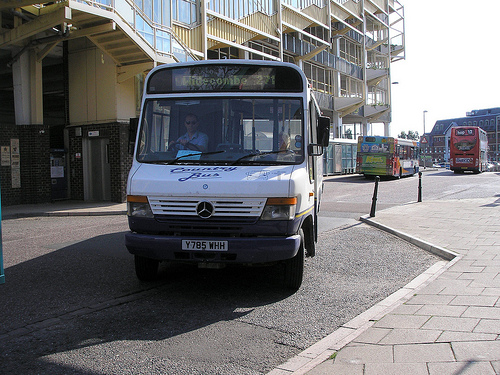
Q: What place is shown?
A: It is a street.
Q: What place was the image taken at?
A: It was taken at the street.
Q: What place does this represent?
A: It represents the street.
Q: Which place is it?
A: It is a street.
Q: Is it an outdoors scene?
A: Yes, it is outdoors.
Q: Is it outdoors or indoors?
A: It is outdoors.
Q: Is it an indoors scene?
A: No, it is outdoors.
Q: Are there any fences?
A: No, there are no fences.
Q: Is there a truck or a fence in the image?
A: No, there are no fences or trucks.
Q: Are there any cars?
A: No, there are no cars.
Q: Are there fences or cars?
A: No, there are no cars or fences.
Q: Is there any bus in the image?
A: Yes, there is a bus.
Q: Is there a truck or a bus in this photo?
A: Yes, there is a bus.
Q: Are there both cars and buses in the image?
A: No, there is a bus but no cars.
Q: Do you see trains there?
A: No, there are no trains.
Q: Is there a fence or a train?
A: No, there are no trains or fences.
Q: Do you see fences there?
A: No, there are no fences.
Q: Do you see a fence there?
A: No, there are no fences.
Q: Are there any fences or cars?
A: No, there are no fences or cars.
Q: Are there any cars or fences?
A: No, there are no fences or cars.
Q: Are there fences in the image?
A: No, there are no fences.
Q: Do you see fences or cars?
A: No, there are no fences or cars.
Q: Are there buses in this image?
A: Yes, there is a bus.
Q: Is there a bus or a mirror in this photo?
A: Yes, there is a bus.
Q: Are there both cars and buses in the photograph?
A: No, there is a bus but no cars.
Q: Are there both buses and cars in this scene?
A: No, there is a bus but no cars.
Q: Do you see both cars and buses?
A: No, there is a bus but no cars.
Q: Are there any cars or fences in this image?
A: No, there are no fences or cars.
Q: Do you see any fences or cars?
A: No, there are no fences or cars.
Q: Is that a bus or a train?
A: That is a bus.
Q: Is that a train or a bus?
A: That is a bus.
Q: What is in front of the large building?
A: The bus is in front of the building.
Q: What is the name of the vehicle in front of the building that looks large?
A: The vehicle is a bus.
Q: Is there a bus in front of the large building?
A: Yes, there is a bus in front of the building.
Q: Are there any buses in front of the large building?
A: Yes, there is a bus in front of the building.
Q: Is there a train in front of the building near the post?
A: No, there is a bus in front of the building.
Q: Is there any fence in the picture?
A: No, there are no fences.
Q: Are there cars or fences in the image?
A: No, there are no fences or cars.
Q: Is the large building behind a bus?
A: Yes, the building is behind a bus.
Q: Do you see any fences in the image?
A: No, there are no fences.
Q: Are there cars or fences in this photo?
A: No, there are no fences or cars.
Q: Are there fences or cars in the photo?
A: No, there are no fences or cars.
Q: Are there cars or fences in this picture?
A: No, there are no cars or fences.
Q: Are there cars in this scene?
A: No, there are no cars.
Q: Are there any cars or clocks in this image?
A: No, there are no cars or clocks.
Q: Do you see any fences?
A: No, there are no fences.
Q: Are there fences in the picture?
A: No, there are no fences.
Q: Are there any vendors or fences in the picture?
A: No, there are no fences or vendors.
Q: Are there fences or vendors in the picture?
A: No, there are no fences or vendors.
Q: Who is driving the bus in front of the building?
A: The driver is driving the bus.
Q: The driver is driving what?
A: The driver is driving the bus.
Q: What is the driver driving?
A: The driver is driving the bus.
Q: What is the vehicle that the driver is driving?
A: The vehicle is a bus.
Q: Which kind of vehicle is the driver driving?
A: The driver is driving the bus.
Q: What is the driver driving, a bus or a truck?
A: The driver is driving a bus.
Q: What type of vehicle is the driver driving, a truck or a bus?
A: The driver is driving a bus.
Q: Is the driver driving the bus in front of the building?
A: Yes, the driver is driving the bus.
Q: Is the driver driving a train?
A: No, the driver is driving the bus.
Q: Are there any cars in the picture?
A: No, there are no cars.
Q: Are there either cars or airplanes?
A: No, there are no cars or airplanes.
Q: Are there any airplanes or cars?
A: No, there are no cars or airplanes.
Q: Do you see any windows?
A: Yes, there are windows.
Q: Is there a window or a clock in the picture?
A: Yes, there are windows.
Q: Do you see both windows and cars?
A: No, there are windows but no cars.